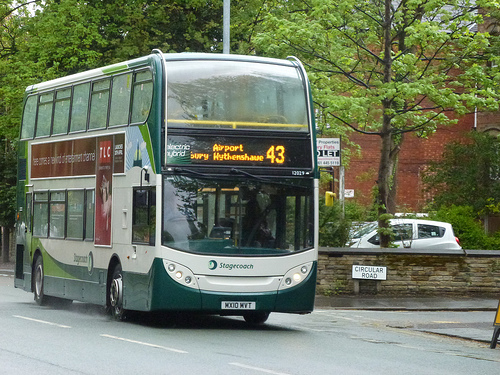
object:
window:
[106, 72, 133, 128]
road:
[0, 271, 498, 372]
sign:
[351, 264, 388, 281]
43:
[266, 145, 286, 165]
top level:
[15, 48, 316, 141]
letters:
[190, 144, 264, 162]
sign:
[315, 138, 341, 168]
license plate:
[221, 300, 256, 310]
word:
[212, 143, 244, 152]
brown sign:
[351, 264, 386, 281]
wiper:
[165, 166, 313, 182]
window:
[34, 89, 56, 140]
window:
[52, 86, 70, 136]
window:
[69, 81, 89, 133]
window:
[88, 79, 108, 131]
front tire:
[106, 262, 139, 321]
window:
[128, 185, 158, 248]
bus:
[12, 48, 334, 321]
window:
[126, 65, 156, 126]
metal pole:
[210, 12, 247, 41]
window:
[64, 188, 83, 235]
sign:
[166, 132, 311, 170]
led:
[189, 142, 286, 164]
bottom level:
[12, 164, 321, 322]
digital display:
[190, 143, 264, 162]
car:
[346, 217, 464, 255]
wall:
[316, 247, 500, 296]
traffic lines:
[0, 308, 281, 375]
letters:
[317, 149, 339, 157]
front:
[155, 48, 320, 316]